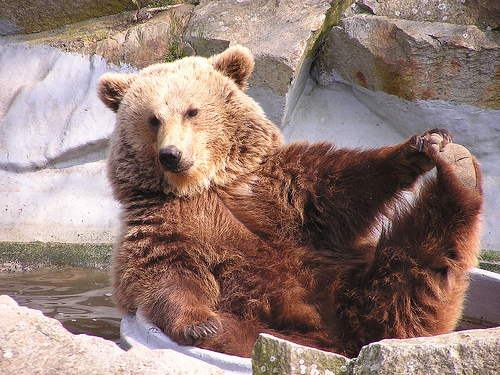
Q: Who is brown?
A: Bear.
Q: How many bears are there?
A: One.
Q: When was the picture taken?
A: Daytime.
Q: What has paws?
A: The bear.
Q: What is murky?
A: The water.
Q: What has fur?
A: A bear.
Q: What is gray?
A: Large rocks.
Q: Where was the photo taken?
A: In a zoo.